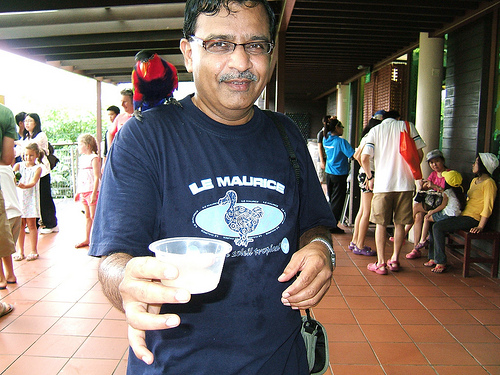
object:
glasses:
[187, 35, 275, 56]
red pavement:
[0, 197, 500, 375]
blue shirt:
[86, 93, 336, 375]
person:
[413, 169, 467, 249]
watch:
[311, 237, 338, 271]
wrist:
[310, 236, 337, 264]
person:
[388, 148, 450, 258]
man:
[88, 0, 337, 375]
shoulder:
[106, 103, 205, 157]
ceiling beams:
[273, 0, 500, 102]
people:
[359, 111, 427, 276]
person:
[74, 133, 102, 248]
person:
[11, 142, 43, 261]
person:
[15, 112, 58, 236]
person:
[105, 87, 134, 152]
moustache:
[218, 69, 257, 85]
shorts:
[368, 190, 414, 225]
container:
[148, 236, 233, 294]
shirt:
[360, 118, 426, 194]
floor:
[368, 285, 474, 368]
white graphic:
[188, 175, 290, 259]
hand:
[278, 243, 335, 310]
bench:
[444, 229, 500, 279]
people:
[422, 153, 499, 273]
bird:
[130, 48, 182, 124]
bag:
[300, 308, 329, 375]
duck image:
[217, 189, 264, 248]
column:
[407, 32, 445, 245]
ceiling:
[265, 0, 500, 102]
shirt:
[459, 177, 496, 222]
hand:
[116, 256, 180, 369]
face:
[202, 23, 269, 106]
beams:
[0, 0, 187, 85]